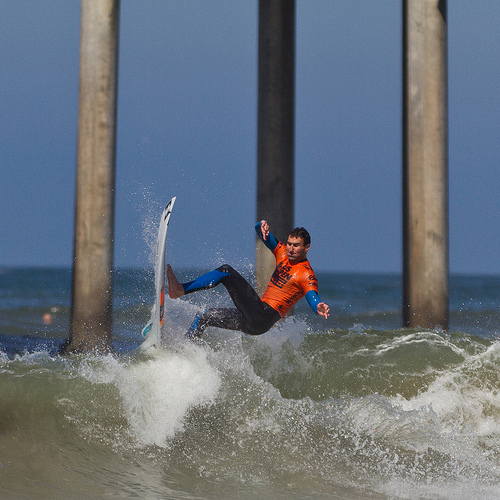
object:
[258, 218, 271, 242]
hand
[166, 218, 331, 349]
man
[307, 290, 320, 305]
sleeve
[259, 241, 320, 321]
orange shirt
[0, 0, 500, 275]
blue sky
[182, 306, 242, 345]
leg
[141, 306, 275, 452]
boar surf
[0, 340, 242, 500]
small wave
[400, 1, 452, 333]
pole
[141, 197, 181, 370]
surf board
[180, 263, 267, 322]
leg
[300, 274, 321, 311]
arm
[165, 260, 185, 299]
foot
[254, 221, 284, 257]
arm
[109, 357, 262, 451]
foam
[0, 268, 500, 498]
ocean